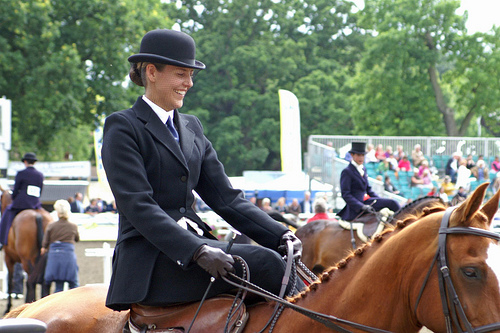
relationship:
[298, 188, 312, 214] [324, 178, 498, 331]
fan watching horses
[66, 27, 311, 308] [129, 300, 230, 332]
lady in saddle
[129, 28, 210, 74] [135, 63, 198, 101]
hat on head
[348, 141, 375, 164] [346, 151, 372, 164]
hat on head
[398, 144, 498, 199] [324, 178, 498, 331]
fans watching horses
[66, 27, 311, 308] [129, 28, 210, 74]
lady wearing hat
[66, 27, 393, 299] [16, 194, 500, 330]
lady riding a horse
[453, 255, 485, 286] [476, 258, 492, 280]
horse's eye brown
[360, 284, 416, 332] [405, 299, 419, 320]
horse's neck brown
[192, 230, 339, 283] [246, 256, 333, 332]
hands holding reins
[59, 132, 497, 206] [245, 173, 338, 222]
group of spectators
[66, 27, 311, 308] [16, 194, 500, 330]
lady on horse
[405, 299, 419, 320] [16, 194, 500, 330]
brown colored horse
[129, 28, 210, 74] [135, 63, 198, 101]
hat on top of head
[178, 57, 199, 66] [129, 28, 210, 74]
ribbon around hat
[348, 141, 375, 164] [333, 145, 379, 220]
hat on man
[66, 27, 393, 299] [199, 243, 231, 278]
lady wearing gloves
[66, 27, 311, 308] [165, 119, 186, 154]
lady wearing tie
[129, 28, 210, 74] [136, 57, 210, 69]
hat has brim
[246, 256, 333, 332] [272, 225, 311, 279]
reins in hand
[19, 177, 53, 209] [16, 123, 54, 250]
number on man